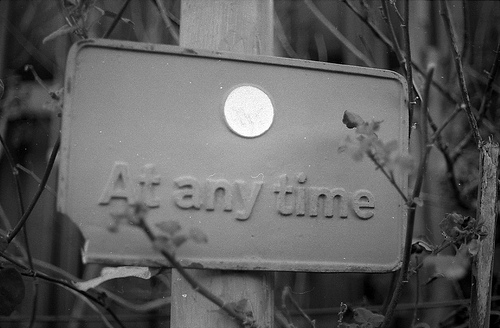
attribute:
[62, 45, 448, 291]
sign — shiny, grey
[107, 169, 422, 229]
letters — raised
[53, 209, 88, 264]
corner — missing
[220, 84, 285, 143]
circle — bright, centered, white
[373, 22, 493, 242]
branches — more, some, black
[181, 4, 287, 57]
pole — thick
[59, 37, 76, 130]
edges — worn, raw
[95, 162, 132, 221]
letter — capitalized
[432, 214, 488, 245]
leaves — small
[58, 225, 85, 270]
edge — gone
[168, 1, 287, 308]
post — tall, wood